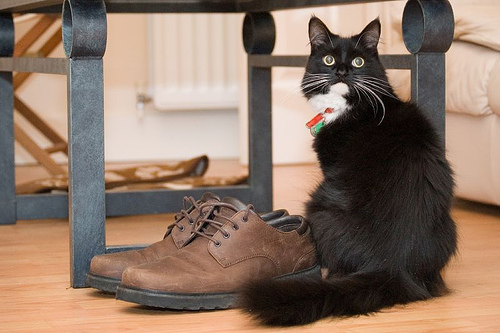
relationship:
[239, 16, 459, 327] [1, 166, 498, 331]
cat on floor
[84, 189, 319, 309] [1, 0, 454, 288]
shoes under table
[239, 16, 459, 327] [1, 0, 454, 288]
cat under table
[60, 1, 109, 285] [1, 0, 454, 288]
leg of table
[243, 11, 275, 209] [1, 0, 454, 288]
leg of table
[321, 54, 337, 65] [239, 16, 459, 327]
eye of a cat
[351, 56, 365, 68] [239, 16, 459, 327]
eye of a cat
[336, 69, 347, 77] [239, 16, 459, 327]
nose of a cat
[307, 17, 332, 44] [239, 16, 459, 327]
ear of a cat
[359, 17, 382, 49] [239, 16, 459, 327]
ear of a cat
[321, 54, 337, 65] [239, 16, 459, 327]
eye of cat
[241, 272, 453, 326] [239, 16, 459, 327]
tail of cat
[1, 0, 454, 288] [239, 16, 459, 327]
table behind cat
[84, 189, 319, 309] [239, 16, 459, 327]
shoes next to cat